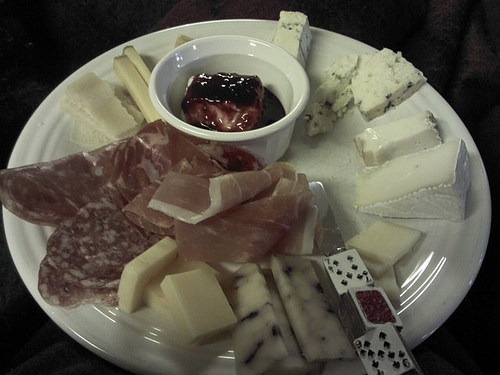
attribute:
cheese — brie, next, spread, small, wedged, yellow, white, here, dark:
[306, 72, 390, 145]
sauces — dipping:
[202, 63, 264, 132]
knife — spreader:
[300, 182, 337, 227]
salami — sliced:
[67, 164, 237, 275]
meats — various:
[30, 133, 299, 296]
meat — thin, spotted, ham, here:
[46, 160, 115, 220]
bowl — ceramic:
[138, 55, 210, 127]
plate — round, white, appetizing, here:
[36, 26, 470, 370]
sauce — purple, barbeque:
[194, 71, 245, 102]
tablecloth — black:
[25, 25, 99, 58]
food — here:
[96, 67, 389, 279]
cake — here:
[427, 174, 463, 198]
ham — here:
[172, 175, 286, 250]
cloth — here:
[399, 3, 497, 59]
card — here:
[350, 325, 391, 351]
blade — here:
[308, 179, 384, 245]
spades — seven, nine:
[329, 259, 378, 282]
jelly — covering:
[237, 96, 289, 124]